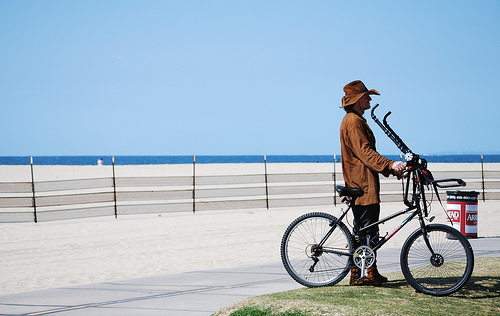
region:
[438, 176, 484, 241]
red and white trash can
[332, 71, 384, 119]
brown floppy hat on mans head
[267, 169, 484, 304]
bike held up by man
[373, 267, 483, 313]
grass with bike shadow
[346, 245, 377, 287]
bike pedal pointing to grass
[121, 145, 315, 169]
water in the distance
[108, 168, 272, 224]
fence in front of beach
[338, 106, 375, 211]
brown jacket on man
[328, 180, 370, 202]
black seat on bike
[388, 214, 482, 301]
front tire on bike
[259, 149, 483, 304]
a man's black bicycle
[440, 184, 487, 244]
a large trash can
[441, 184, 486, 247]
a red and white barrel can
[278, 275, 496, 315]
patchy areas of grass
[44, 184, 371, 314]
a paved trail near the beach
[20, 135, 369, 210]
a see through fence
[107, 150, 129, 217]
a metal fence pole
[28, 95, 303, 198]
a beach scene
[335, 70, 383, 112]
brown hat with wide brim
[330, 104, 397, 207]
a long brown jacket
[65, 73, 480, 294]
man standing near beach path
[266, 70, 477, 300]
man fully dressed near beach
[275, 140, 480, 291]
man holding onto handlebars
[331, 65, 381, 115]
man wearing brown hat with floppy brim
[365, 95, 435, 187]
two long objects on bicycle resembling clarinets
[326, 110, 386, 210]
man wearing long brown jacket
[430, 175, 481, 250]
red and white garbage can behind bicycle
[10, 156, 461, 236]
partition on sand at the beach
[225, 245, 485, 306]
wheels on grassy patch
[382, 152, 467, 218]
assorted straps and frames hanging from handlebars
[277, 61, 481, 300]
Man holding a bike upright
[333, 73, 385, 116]
Man wearing a brown floppy hat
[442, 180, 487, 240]
Red and white trash can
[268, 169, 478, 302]
Black bicycle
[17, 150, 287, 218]
Fencing standing in the sand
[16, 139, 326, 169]
Ocean water in the distance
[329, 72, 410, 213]
Man wearing a brown coat and hat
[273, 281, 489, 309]
Patch of grass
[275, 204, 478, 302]
Two black round bicycle tires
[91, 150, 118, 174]
A person sitting in the sand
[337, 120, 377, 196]
the jacket is brown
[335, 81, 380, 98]
the hat is brown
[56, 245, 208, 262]
the sand is white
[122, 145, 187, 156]
the sea is blue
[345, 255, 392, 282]
the shoes are brown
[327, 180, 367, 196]
the seat is black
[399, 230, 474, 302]
the tire is black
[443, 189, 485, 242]
the trash can has a red drawing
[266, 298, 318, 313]
the ground has patches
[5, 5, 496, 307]
the photo is a daytime one